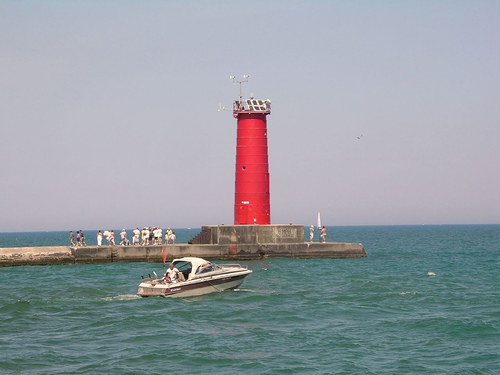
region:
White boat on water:
[135, 252, 259, 304]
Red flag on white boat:
[152, 244, 176, 266]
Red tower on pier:
[230, 116, 281, 236]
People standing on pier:
[63, 222, 190, 255]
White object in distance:
[311, 204, 326, 234]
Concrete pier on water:
[0, 219, 370, 285]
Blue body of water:
[0, 223, 499, 373]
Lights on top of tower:
[218, 71, 256, 103]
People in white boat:
[155, 265, 184, 292]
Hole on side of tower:
[235, 157, 250, 175]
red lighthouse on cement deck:
[192, 72, 323, 279]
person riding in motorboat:
[94, 253, 344, 335]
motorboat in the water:
[124, 257, 316, 333]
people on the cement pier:
[13, 208, 207, 289]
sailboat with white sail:
[302, 186, 354, 231]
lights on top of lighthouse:
[206, 59, 313, 236]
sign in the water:
[127, 240, 187, 276]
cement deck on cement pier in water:
[84, 214, 357, 270]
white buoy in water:
[395, 250, 471, 316]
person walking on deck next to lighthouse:
[234, 124, 270, 259]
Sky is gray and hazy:
[0, 3, 499, 228]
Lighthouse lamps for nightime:
[225, 66, 250, 96]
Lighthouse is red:
[229, 97, 276, 224]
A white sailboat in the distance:
[310, 210, 333, 229]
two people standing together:
[306, 223, 330, 241]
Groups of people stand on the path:
[62, 222, 181, 246]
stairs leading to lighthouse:
[183, 221, 213, 241]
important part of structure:
[229, 92, 278, 114]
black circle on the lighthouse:
[235, 157, 247, 172]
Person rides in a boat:
[134, 254, 250, 298]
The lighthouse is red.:
[184, 68, 340, 249]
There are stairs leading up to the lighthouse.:
[186, 56, 309, 253]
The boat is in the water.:
[121, 244, 265, 319]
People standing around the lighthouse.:
[38, 62, 308, 258]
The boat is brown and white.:
[111, 239, 272, 321]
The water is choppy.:
[0, 208, 497, 373]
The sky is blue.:
[0, 2, 498, 228]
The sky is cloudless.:
[1, 1, 498, 239]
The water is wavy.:
[0, 220, 499, 373]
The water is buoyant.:
[1, 224, 499, 371]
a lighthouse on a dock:
[222, 65, 282, 237]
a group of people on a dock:
[59, 217, 176, 255]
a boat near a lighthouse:
[130, 69, 330, 310]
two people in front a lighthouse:
[216, 68, 337, 250]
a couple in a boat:
[131, 251, 256, 303]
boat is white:
[127, 251, 259, 306]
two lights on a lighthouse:
[218, 65, 279, 130]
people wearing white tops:
[93, 220, 186, 250]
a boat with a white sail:
[306, 201, 330, 248]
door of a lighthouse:
[228, 190, 259, 229]